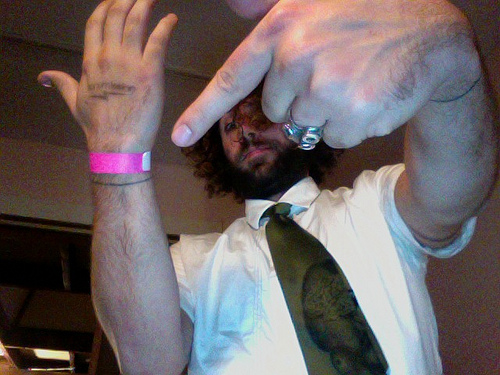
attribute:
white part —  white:
[141, 150, 153, 172]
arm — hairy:
[89, 174, 194, 374]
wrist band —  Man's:
[83, 142, 157, 179]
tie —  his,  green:
[259, 205, 386, 372]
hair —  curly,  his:
[176, 83, 343, 184]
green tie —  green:
[260, 199, 387, 373]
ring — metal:
[279, 112, 326, 150]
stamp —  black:
[72, 72, 141, 111]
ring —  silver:
[283, 107, 324, 149]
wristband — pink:
[85, 144, 154, 179]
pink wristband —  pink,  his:
[87, 150, 152, 175]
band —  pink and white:
[84, 152, 152, 174]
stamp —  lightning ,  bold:
[85, 81, 135, 102]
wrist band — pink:
[85, 149, 152, 173]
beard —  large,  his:
[198, 148, 348, 203]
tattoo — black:
[85, 80, 136, 101]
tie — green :
[272, 210, 387, 374]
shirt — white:
[190, 171, 464, 358]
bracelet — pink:
[83, 146, 156, 177]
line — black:
[89, 172, 151, 194]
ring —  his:
[279, 105, 329, 152]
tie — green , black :
[273, 285, 328, 346]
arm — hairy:
[30, 0, 197, 375]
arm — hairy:
[384, 0, 489, 253]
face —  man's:
[179, 72, 348, 192]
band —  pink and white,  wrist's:
[87, 151, 156, 171]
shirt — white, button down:
[171, 160, 474, 372]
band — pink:
[87, 145, 152, 177]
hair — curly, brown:
[194, 124, 332, 200]